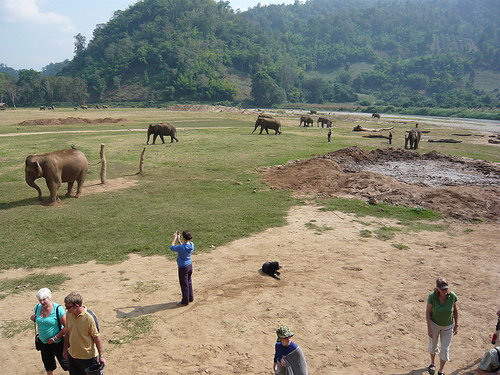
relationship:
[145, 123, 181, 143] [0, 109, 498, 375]
elephant in field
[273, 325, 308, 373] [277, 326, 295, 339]
boy has hat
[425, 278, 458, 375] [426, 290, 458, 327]
woman has shirt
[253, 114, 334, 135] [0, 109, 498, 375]
elephants in field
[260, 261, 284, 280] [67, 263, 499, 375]
dog on ground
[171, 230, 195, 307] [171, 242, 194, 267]
woman wearing shirt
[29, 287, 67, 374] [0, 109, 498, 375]
woman in field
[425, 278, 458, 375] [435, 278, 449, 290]
woman has visor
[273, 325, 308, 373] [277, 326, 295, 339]
boy wearing hat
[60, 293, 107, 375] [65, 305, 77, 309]
man has sunglasses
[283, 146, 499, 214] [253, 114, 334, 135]
watering hole near elephants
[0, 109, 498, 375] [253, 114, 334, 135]
field with elephants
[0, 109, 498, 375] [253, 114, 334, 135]
field has elephants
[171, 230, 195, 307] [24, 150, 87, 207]
woman looking at elephant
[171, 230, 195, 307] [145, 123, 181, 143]
woman photographing elephant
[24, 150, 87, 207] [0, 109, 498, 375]
elephant standing in field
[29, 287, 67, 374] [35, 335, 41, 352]
woman has handbag